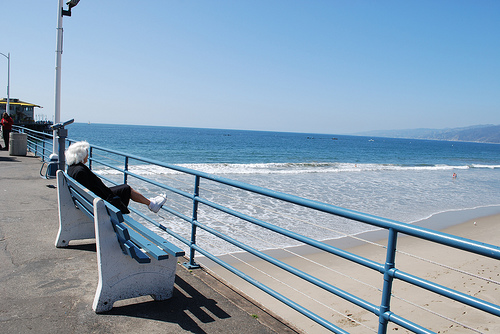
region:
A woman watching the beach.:
[60, 136, 172, 231]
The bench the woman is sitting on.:
[51, 161, 198, 305]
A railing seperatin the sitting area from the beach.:
[8, 116, 492, 333]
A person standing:
[2, 109, 14, 151]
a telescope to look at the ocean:
[47, 119, 87, 177]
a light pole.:
[0, 42, 15, 139]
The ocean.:
[84, 124, 498, 235]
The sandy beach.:
[203, 212, 495, 331]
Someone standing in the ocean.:
[449, 167, 459, 184]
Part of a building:
[2, 89, 40, 135]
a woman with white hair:
[55, 138, 177, 228]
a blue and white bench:
[32, 162, 192, 327]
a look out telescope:
[42, 109, 74, 190]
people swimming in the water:
[440, 168, 465, 183]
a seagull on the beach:
[462, 215, 490, 230]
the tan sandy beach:
[200, 204, 493, 329]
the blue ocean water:
[46, 118, 493, 170]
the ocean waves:
[97, 155, 492, 187]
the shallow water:
[112, 175, 492, 237]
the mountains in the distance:
[344, 117, 499, 146]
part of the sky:
[321, 27, 383, 109]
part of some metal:
[267, 238, 316, 299]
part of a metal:
[27, 261, 74, 306]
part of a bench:
[115, 206, 165, 259]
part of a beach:
[391, 261, 420, 296]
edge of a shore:
[311, 218, 369, 266]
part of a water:
[343, 162, 393, 207]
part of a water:
[333, 130, 368, 157]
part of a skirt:
[113, 181, 136, 212]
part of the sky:
[220, 10, 283, 92]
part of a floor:
[30, 261, 70, 297]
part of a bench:
[160, 241, 204, 268]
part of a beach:
[329, 235, 375, 285]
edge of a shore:
[353, 212, 400, 236]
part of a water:
[336, 149, 380, 176]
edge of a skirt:
[113, 177, 137, 214]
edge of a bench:
[89, 255, 111, 299]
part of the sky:
[266, 1, 309, 46]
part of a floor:
[12, 250, 57, 302]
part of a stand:
[348, 269, 383, 299]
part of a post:
[179, 196, 221, 263]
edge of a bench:
[71, 243, 115, 309]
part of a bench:
[121, 256, 179, 311]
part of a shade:
[202, 277, 228, 308]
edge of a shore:
[328, 215, 365, 233]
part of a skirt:
[108, 182, 126, 204]